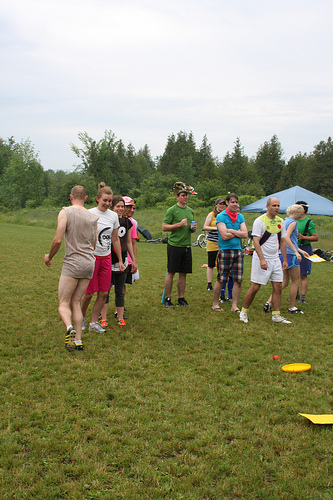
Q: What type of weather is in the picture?
A: It is cloudy.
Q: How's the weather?
A: It is cloudy.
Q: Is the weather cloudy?
A: Yes, it is cloudy.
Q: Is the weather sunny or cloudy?
A: It is cloudy.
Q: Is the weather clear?
A: No, it is cloudy.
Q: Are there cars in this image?
A: No, there are no cars.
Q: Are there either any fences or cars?
A: No, there are no cars or fences.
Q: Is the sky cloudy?
A: Yes, the sky is cloudy.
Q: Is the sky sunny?
A: No, the sky is cloudy.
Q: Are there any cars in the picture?
A: No, there are no cars.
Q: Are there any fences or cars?
A: No, there are no cars or fences.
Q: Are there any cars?
A: No, there are no cars.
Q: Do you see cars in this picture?
A: No, there are no cars.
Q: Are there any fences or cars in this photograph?
A: No, there are no cars or fences.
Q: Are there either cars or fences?
A: No, there are no cars or fences.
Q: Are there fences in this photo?
A: No, there are no fences.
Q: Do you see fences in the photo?
A: No, there are no fences.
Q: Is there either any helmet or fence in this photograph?
A: No, there are no fences or helmets.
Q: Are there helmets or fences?
A: No, there are no fences or helmets.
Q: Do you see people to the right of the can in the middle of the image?
A: Yes, there is a person to the right of the can.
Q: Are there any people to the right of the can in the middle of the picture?
A: Yes, there is a person to the right of the can.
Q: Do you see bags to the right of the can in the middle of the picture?
A: No, there is a person to the right of the can.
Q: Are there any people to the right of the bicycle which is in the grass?
A: Yes, there is a person to the right of the bicycle.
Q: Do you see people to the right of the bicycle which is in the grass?
A: Yes, there is a person to the right of the bicycle.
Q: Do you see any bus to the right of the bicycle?
A: No, there is a person to the right of the bicycle.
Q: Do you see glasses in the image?
A: No, there are no glasses.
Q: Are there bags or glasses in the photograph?
A: No, there are no glasses or bags.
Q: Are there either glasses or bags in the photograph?
A: No, there are no glasses or bags.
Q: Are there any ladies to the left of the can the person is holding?
A: Yes, there is a lady to the left of the can.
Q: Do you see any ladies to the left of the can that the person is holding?
A: Yes, there is a lady to the left of the can.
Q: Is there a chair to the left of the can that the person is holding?
A: No, there is a lady to the left of the can.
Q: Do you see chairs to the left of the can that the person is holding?
A: No, there is a lady to the left of the can.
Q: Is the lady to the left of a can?
A: Yes, the lady is to the left of a can.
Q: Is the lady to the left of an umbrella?
A: No, the lady is to the left of a can.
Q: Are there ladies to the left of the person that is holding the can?
A: Yes, there is a lady to the left of the person.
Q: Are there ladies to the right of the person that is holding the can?
A: No, the lady is to the left of the person.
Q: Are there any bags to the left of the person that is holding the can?
A: No, there is a lady to the left of the person.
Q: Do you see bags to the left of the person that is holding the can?
A: No, there is a lady to the left of the person.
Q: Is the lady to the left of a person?
A: Yes, the lady is to the left of a person.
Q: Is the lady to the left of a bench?
A: No, the lady is to the left of a person.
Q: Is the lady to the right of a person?
A: No, the lady is to the left of a person.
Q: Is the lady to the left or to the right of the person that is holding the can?
A: The lady is to the left of the person.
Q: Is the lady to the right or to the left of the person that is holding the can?
A: The lady is to the left of the person.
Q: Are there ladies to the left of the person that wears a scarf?
A: Yes, there is a lady to the left of the person.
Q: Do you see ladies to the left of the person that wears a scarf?
A: Yes, there is a lady to the left of the person.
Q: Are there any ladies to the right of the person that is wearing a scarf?
A: No, the lady is to the left of the person.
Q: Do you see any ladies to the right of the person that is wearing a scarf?
A: No, the lady is to the left of the person.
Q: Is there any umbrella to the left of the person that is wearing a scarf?
A: No, there is a lady to the left of the person.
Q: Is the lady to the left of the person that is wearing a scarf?
A: Yes, the lady is to the left of the person.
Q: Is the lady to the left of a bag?
A: No, the lady is to the left of the person.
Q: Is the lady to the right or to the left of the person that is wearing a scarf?
A: The lady is to the left of the person.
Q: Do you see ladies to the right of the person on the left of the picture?
A: Yes, there is a lady to the right of the person.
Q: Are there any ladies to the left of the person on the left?
A: No, the lady is to the right of the person.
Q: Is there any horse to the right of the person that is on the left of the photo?
A: No, there is a lady to the right of the person.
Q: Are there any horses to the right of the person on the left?
A: No, there is a lady to the right of the person.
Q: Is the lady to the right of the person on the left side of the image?
A: Yes, the lady is to the right of the person.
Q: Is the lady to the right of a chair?
A: No, the lady is to the right of the person.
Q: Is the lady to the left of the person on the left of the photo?
A: No, the lady is to the right of the person.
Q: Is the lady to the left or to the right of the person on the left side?
A: The lady is to the right of the person.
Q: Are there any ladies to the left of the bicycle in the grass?
A: Yes, there is a lady to the left of the bicycle.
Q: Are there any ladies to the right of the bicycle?
A: No, the lady is to the left of the bicycle.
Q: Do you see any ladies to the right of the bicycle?
A: No, the lady is to the left of the bicycle.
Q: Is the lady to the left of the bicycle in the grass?
A: Yes, the lady is to the left of the bicycle.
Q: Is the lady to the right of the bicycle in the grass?
A: No, the lady is to the left of the bicycle.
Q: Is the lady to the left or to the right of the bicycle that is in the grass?
A: The lady is to the left of the bicycle.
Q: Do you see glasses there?
A: No, there are no glasses.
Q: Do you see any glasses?
A: No, there are no glasses.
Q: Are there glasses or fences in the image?
A: No, there are no glasses or fences.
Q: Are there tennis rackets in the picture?
A: No, there are no tennis rackets.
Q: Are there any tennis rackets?
A: No, there are no tennis rackets.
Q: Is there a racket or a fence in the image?
A: No, there are no rackets or fences.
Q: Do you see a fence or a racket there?
A: No, there are no rackets or fences.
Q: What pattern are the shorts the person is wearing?
A: The shorts are checkered.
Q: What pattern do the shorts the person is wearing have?
A: The shorts have checkered pattern.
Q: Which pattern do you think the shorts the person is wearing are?
A: The shorts are checkered.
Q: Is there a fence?
A: No, there are no fences.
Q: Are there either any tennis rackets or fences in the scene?
A: No, there are no fences or tennis rackets.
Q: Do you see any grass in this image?
A: Yes, there is grass.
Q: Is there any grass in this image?
A: Yes, there is grass.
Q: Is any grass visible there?
A: Yes, there is grass.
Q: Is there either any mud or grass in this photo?
A: Yes, there is grass.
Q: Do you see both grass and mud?
A: No, there is grass but no mud.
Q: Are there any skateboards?
A: No, there are no skateboards.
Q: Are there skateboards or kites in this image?
A: No, there are no skateboards or kites.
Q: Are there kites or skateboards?
A: No, there are no skateboards or kites.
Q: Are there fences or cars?
A: No, there are no cars or fences.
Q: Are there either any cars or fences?
A: No, there are no cars or fences.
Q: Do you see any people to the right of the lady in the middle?
A: Yes, there is a person to the right of the lady.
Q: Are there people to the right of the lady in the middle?
A: Yes, there is a person to the right of the lady.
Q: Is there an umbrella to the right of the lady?
A: No, there is a person to the right of the lady.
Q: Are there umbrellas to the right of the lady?
A: No, there is a person to the right of the lady.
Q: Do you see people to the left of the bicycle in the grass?
A: Yes, there is a person to the left of the bicycle.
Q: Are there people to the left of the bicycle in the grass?
A: Yes, there is a person to the left of the bicycle.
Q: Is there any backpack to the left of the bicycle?
A: No, there is a person to the left of the bicycle.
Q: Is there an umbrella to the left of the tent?
A: No, there is a person to the left of the tent.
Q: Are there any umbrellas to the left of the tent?
A: No, there is a person to the left of the tent.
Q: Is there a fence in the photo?
A: No, there are no fences.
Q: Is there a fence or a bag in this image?
A: No, there are no fences or bags.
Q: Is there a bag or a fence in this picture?
A: No, there are no fences or bags.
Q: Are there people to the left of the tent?
A: Yes, there is a person to the left of the tent.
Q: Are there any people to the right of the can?
A: Yes, there is a person to the right of the can.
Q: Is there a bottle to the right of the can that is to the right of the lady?
A: No, there is a person to the right of the can.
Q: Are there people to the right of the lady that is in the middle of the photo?
A: Yes, there is a person to the right of the lady.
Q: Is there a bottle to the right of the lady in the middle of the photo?
A: No, there is a person to the right of the lady.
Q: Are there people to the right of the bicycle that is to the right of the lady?
A: Yes, there is a person to the right of the bicycle.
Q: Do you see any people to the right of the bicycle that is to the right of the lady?
A: Yes, there is a person to the right of the bicycle.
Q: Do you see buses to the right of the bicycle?
A: No, there is a person to the right of the bicycle.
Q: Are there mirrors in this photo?
A: No, there are no mirrors.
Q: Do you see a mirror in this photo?
A: No, there are no mirrors.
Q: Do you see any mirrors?
A: No, there are no mirrors.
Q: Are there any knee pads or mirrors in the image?
A: No, there are no mirrors or knee pads.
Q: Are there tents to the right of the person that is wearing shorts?
A: Yes, there is a tent to the right of the person.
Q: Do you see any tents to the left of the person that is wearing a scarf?
A: No, the tent is to the right of the person.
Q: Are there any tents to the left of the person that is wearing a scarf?
A: No, the tent is to the right of the person.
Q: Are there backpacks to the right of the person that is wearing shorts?
A: No, there is a tent to the right of the person.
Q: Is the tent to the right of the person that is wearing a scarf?
A: Yes, the tent is to the right of the person.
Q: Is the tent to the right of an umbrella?
A: No, the tent is to the right of the person.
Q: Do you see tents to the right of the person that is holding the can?
A: Yes, there is a tent to the right of the person.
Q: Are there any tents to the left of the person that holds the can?
A: No, the tent is to the right of the person.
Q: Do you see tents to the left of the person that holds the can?
A: No, the tent is to the right of the person.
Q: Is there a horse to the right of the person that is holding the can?
A: No, there is a tent to the right of the person.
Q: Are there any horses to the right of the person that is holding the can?
A: No, there is a tent to the right of the person.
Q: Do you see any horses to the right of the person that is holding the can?
A: No, there is a tent to the right of the person.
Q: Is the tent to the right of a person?
A: Yes, the tent is to the right of a person.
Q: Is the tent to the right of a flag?
A: No, the tent is to the right of a person.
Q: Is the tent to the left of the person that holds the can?
A: No, the tent is to the right of the person.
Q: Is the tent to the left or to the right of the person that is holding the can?
A: The tent is to the right of the person.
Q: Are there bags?
A: No, there are no bags.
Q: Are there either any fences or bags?
A: No, there are no bags or fences.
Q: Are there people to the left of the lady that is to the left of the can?
A: Yes, there is a person to the left of the lady.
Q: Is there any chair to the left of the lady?
A: No, there is a person to the left of the lady.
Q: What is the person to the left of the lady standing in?
A: The person is standing in the grass.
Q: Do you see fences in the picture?
A: No, there are no fences.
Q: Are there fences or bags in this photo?
A: No, there are no fences or bags.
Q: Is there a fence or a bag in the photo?
A: No, there are no fences or bags.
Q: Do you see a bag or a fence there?
A: No, there are no fences or bags.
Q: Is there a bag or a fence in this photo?
A: No, there are no fences or bags.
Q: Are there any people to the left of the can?
A: Yes, there is a person to the left of the can.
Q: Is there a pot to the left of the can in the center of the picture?
A: No, there is a person to the left of the can.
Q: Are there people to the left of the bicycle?
A: Yes, there is a person to the left of the bicycle.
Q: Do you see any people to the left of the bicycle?
A: Yes, there is a person to the left of the bicycle.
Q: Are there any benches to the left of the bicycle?
A: No, there is a person to the left of the bicycle.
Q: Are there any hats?
A: Yes, there is a hat.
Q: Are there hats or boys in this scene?
A: Yes, there is a hat.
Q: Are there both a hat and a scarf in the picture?
A: Yes, there are both a hat and a scarf.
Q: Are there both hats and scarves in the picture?
A: Yes, there are both a hat and a scarf.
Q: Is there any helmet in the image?
A: No, there are no helmets.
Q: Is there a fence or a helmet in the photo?
A: No, there are no helmets or fences.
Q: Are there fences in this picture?
A: No, there are no fences.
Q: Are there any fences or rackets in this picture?
A: No, there are no fences or rackets.